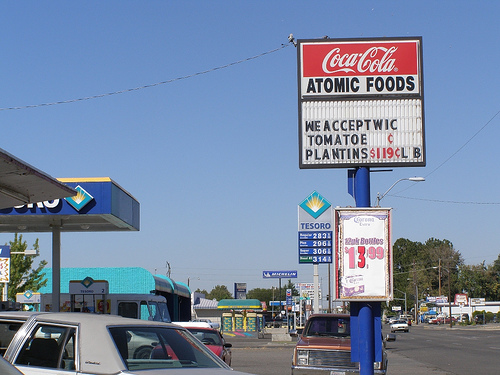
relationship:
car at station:
[5, 308, 241, 358] [6, 150, 395, 368]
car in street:
[390, 318, 407, 330] [199, 295, 491, 374]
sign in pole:
[293, 37, 430, 167] [350, 167, 376, 373]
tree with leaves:
[390, 233, 494, 314] [392, 239, 495, 299]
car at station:
[297, 312, 390, 370] [3, 144, 497, 372]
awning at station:
[2, 176, 144, 234] [3, 144, 497, 372]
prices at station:
[293, 205, 334, 262] [3, 144, 497, 372]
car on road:
[390, 319, 410, 333] [212, 306, 492, 367]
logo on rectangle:
[318, 44, 399, 75] [297, 39, 418, 79]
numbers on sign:
[311, 228, 332, 264] [296, 190, 336, 266]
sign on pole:
[336, 205, 393, 301] [348, 171, 379, 371]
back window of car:
[107, 324, 223, 368] [0, 302, 254, 369]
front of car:
[292, 308, 362, 369] [289, 312, 389, 374]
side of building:
[75, 268, 148, 292] [26, 263, 194, 323]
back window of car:
[107, 324, 222, 368] [0, 311, 236, 371]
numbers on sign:
[372, 145, 393, 160] [293, 37, 430, 167]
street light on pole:
[406, 171, 429, 185] [381, 176, 410, 195]